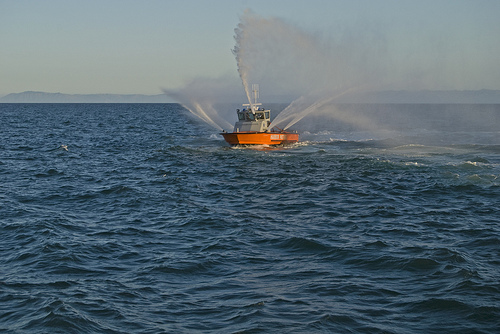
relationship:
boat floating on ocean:
[218, 101, 300, 154] [0, 104, 500, 334]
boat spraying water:
[218, 101, 300, 154] [225, 19, 272, 105]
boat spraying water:
[218, 101, 300, 154] [274, 91, 355, 129]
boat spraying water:
[218, 101, 300, 154] [163, 85, 227, 135]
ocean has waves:
[0, 104, 500, 334] [277, 228, 447, 275]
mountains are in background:
[339, 88, 500, 112] [1, 2, 497, 106]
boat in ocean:
[218, 101, 300, 154] [0, 104, 500, 334]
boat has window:
[218, 101, 300, 154] [237, 112, 246, 121]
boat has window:
[218, 101, 300, 154] [245, 112, 256, 121]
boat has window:
[218, 101, 300, 154] [257, 112, 266, 121]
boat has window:
[218, 101, 300, 154] [264, 112, 269, 121]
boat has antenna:
[218, 101, 300, 154] [243, 80, 266, 108]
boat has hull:
[218, 101, 300, 154] [222, 130, 269, 150]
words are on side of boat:
[264, 133, 291, 142] [218, 101, 300, 154]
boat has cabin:
[218, 101, 300, 154] [234, 114, 275, 135]